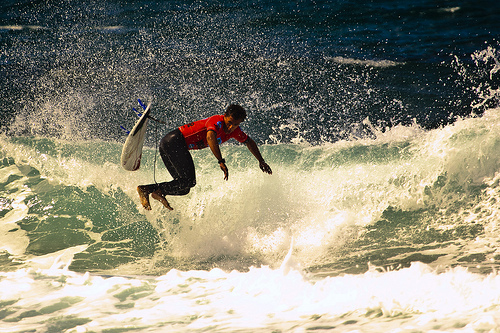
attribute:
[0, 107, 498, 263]
wave — white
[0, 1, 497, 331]
waters — raging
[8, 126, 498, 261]
wave — white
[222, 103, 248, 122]
hair — dark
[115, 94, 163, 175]
surfboard — white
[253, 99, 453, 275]
foam — white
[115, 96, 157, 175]
surfboard — white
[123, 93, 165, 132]
fin — small, blue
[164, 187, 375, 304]
wave — white , bright 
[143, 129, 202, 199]
wetsuit — dark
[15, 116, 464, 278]
wave — white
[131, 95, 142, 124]
handles — blue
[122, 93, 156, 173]
surfboard — white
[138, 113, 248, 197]
water suit — red, black